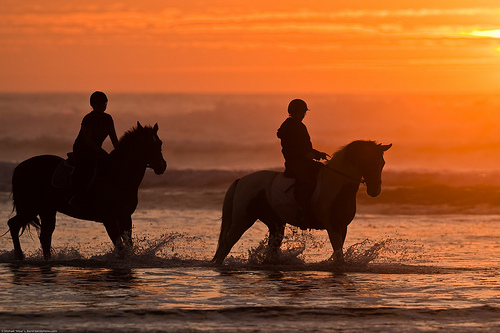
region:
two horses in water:
[53, 58, 400, 283]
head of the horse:
[351, 125, 412, 208]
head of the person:
[263, 76, 335, 139]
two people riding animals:
[47, 75, 355, 180]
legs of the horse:
[178, 226, 298, 285]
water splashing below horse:
[261, 230, 322, 287]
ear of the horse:
[382, 134, 399, 159]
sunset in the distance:
[386, 64, 476, 113]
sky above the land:
[137, 13, 229, 72]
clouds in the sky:
[200, 10, 302, 98]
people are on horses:
[27, 91, 437, 271]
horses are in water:
[27, 71, 364, 284]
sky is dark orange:
[245, 2, 440, 117]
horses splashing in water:
[80, 218, 207, 282]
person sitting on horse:
[65, 82, 136, 202]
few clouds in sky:
[73, 16, 273, 141]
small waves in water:
[125, 84, 218, 244]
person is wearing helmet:
[276, 93, 311, 121]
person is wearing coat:
[262, 120, 294, 157]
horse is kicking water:
[254, 226, 308, 278]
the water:
[192, 284, 218, 314]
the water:
[237, 289, 278, 327]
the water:
[200, 286, 240, 328]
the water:
[245, 268, 300, 317]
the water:
[217, 294, 245, 331]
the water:
[289, 313, 318, 325]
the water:
[267, 286, 338, 323]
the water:
[320, 322, 339, 330]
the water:
[314, 288, 351, 322]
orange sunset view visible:
[379, 11, 498, 138]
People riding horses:
[14, 74, 417, 268]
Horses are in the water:
[16, 70, 420, 299]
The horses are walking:
[28, 55, 399, 276]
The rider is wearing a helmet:
[256, 86, 349, 186]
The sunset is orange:
[75, 17, 480, 178]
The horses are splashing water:
[14, 219, 424, 279]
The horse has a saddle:
[261, 136, 333, 211]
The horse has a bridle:
[308, 128, 395, 206]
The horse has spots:
[196, 111, 396, 284]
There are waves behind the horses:
[44, 68, 434, 215]